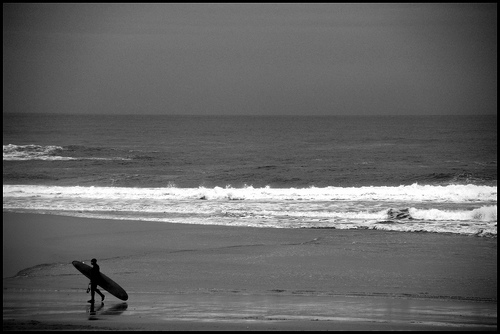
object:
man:
[84, 258, 107, 303]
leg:
[95, 287, 104, 295]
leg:
[88, 287, 96, 300]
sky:
[0, 1, 499, 116]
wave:
[3, 180, 497, 235]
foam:
[2, 175, 499, 237]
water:
[0, 114, 499, 240]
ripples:
[0, 158, 498, 189]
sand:
[0, 210, 499, 334]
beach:
[0, 218, 497, 332]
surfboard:
[71, 260, 131, 302]